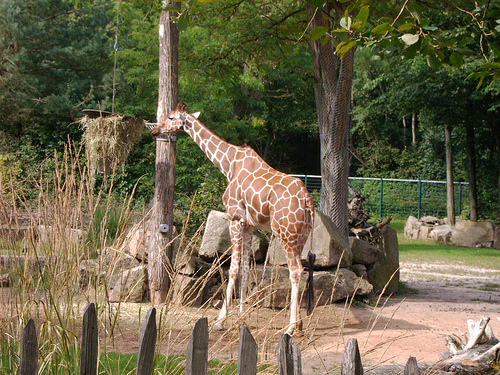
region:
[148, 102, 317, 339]
A standing giraffe.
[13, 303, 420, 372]
Wooden fence.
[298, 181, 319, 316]
A tail of a giraffe.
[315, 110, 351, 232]
A trunk of a tree.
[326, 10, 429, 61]
Green leaves.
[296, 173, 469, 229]
Green fence in the background.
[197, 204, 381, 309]
Rocks on the field.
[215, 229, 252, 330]
Front legs of a giraffe.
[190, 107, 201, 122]
Right ear of a giraffe.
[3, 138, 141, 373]
Brown plants in the foreground.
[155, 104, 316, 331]
brown and white giraffe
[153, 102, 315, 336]
giraffe standing on ground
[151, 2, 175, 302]
brown wood tree trunk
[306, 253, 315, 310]
black tail on giraffe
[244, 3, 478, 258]
tree with green leaves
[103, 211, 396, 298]
grey boulders on ground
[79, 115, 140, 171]
hay bale hanging on tree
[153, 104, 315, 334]
giraffe eating from hay bale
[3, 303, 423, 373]
grey wood fence stakes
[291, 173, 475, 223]
green metal chain link fence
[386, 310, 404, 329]
part of a shade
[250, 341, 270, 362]
edge of a ple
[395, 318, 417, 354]
part of a ground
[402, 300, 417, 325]
part of a ground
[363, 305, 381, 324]
part of a ground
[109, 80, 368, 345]
a giraffe in the zoo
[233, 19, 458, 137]
trees with its branches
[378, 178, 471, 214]
green color steel fencing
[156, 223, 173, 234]
bolt in the tree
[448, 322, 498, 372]
dry wood in the floor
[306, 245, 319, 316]
tail of the giraffe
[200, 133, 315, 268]
brown polygons on a cream colored giraffe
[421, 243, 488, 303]
dirt with green grass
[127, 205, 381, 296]
stones and trees near the giraffe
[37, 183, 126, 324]
brown color grass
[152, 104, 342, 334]
A tall giraffe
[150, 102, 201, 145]
A head of the giraffe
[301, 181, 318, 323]
A long tail of the giraffe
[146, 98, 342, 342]
A giraffe at the zoo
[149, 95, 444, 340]
A giraffe in captivity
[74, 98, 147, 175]
Hay for the giraffe to eat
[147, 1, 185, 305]
A tall brown pole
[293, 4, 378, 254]
A tree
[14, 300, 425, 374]
A brown staked fence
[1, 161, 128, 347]
Tall brown grass